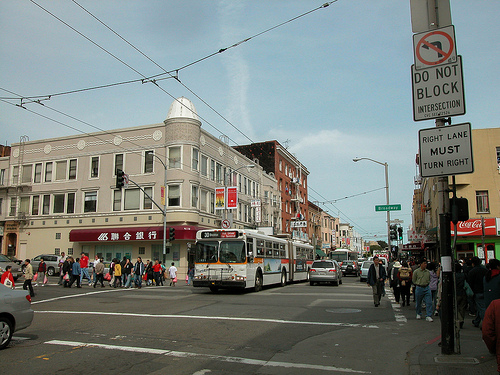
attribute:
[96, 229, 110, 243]
letter — chinese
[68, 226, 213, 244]
awning — maroon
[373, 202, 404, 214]
sign — green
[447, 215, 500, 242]
sign — red, rectangular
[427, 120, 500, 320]
building — store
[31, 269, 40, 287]
bag — pink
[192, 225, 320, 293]
bus — white, moving, big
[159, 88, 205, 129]
dome — white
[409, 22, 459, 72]
sign — square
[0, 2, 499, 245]
sky — clear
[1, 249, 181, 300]
people — walking, crossing street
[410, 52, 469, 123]
sign — white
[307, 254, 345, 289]
car — silver, moving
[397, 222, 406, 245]
streetlight — on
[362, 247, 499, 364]
people — walking